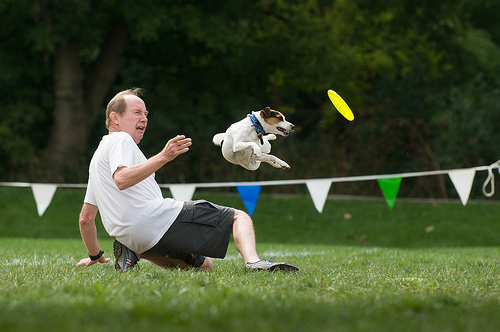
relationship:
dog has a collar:
[213, 106, 295, 171] [247, 109, 267, 140]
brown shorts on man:
[158, 197, 234, 260] [78, 89, 300, 275]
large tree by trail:
[2, 2, 98, 186] [226, 189, 498, 206]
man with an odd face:
[78, 89, 300, 275] [117, 94, 150, 142]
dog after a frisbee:
[213, 106, 295, 171] [327, 90, 358, 122]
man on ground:
[78, 89, 300, 275] [1, 271, 500, 330]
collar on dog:
[247, 109, 267, 140] [213, 106, 295, 171]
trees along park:
[1, 2, 500, 89] [1, 0, 498, 331]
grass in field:
[1, 271, 500, 330] [0, 186, 500, 330]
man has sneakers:
[78, 89, 300, 275] [109, 240, 140, 272]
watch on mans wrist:
[89, 249, 105, 260] [85, 245, 110, 265]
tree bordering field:
[2, 2, 98, 186] [0, 186, 500, 330]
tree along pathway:
[2, 2, 98, 186] [251, 185, 499, 210]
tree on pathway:
[2, 2, 98, 186] [251, 185, 499, 210]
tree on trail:
[2, 2, 98, 186] [226, 189, 498, 206]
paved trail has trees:
[226, 189, 498, 206] [1, 2, 500, 89]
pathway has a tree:
[226, 189, 498, 206] [2, 2, 98, 186]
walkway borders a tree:
[226, 189, 498, 206] [2, 2, 98, 186]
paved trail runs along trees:
[226, 189, 498, 206] [1, 2, 500, 89]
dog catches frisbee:
[213, 106, 295, 171] [327, 90, 358, 122]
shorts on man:
[158, 197, 234, 260] [78, 89, 300, 275]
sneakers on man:
[109, 240, 140, 272] [78, 89, 300, 275]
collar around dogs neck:
[247, 109, 267, 140] [250, 111, 275, 142]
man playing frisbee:
[78, 89, 300, 275] [327, 90, 358, 122]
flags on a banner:
[449, 168, 477, 211] [249, 170, 498, 217]